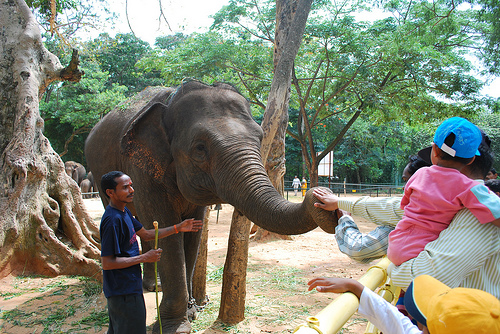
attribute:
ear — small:
[426, 141, 439, 159]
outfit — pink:
[408, 170, 455, 250]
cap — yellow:
[431, 117, 483, 158]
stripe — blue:
[400, 280, 425, 329]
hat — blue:
[434, 115, 481, 164]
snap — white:
[440, 140, 455, 155]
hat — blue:
[425, 110, 486, 159]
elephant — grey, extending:
[81, 77, 342, 320]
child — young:
[306, 273, 499, 331]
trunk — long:
[214, 145, 341, 235]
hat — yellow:
[404, 267, 499, 330]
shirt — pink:
[389, 170, 492, 253]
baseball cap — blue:
[418, 105, 497, 171]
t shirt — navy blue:
[98, 202, 143, 299]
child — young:
[382, 115, 488, 270]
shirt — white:
[352, 284, 421, 332]